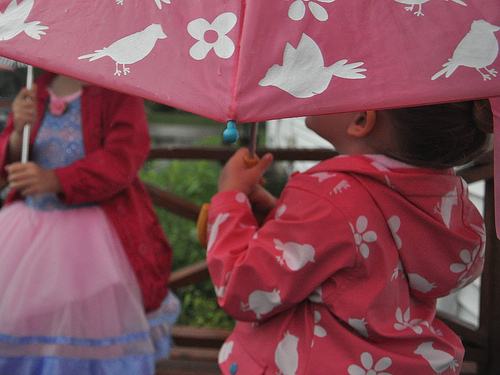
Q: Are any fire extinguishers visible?
A: No, there are no fire extinguishers.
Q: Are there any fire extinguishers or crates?
A: No, there are no fire extinguishers or crates.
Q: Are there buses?
A: No, there are no buses.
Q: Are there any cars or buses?
A: No, there are no buses or cars.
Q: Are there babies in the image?
A: Yes, there is a baby.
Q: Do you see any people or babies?
A: Yes, there is a baby.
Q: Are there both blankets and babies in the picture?
A: No, there is a baby but no blankets.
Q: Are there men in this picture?
A: No, there are no men.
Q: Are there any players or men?
A: No, there are no men or players.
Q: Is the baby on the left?
A: Yes, the baby is on the left of the image.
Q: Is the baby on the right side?
A: No, the baby is on the left of the image.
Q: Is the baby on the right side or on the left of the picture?
A: The baby is on the left of the image.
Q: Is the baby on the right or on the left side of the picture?
A: The baby is on the left of the image.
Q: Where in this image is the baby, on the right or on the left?
A: The baby is on the left of the image.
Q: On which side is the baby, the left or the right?
A: The baby is on the left of the image.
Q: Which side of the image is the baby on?
A: The baby is on the left of the image.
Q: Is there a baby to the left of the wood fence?
A: Yes, there is a baby to the left of the fence.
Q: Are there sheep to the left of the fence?
A: No, there is a baby to the left of the fence.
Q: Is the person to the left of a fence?
A: Yes, the baby is to the left of a fence.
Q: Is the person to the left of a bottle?
A: No, the baby is to the left of a fence.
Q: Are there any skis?
A: No, there are no skis.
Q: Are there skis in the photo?
A: No, there are no skis.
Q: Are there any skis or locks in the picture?
A: No, there are no skis or locks.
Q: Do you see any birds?
A: Yes, there is a bird.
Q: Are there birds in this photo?
A: Yes, there is a bird.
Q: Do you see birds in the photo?
A: Yes, there is a bird.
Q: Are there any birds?
A: Yes, there is a bird.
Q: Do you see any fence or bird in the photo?
A: Yes, there is a bird.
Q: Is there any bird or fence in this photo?
A: Yes, there is a bird.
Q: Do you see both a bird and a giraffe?
A: No, there is a bird but no giraffes.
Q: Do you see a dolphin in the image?
A: No, there are no dolphins.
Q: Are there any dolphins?
A: No, there are no dolphins.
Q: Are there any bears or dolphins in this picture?
A: No, there are no dolphins or bears.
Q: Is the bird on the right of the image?
A: No, the bird is on the left of the image.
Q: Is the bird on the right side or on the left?
A: The bird is on the left of the image.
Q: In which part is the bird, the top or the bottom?
A: The bird is in the top of the image.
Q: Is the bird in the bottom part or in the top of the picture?
A: The bird is in the top of the image.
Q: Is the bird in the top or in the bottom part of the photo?
A: The bird is in the top of the image.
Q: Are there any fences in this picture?
A: Yes, there is a fence.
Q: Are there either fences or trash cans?
A: Yes, there is a fence.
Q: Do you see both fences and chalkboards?
A: No, there is a fence but no chalkboards.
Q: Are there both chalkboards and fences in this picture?
A: No, there is a fence but no chalkboards.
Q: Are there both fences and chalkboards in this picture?
A: No, there is a fence but no chalkboards.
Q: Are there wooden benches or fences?
A: Yes, there is a wood fence.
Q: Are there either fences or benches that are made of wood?
A: Yes, the fence is made of wood.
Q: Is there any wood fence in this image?
A: Yes, there is a wood fence.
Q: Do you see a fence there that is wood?
A: Yes, there is a wood fence.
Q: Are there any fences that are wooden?
A: Yes, there is a fence that is wooden.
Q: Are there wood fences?
A: Yes, there is a fence that is made of wood.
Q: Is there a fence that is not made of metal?
A: Yes, there is a fence that is made of wood.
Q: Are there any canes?
A: No, there are no canes.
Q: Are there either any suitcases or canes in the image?
A: No, there are no canes or suitcases.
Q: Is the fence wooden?
A: Yes, the fence is wooden.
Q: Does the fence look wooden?
A: Yes, the fence is wooden.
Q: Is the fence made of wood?
A: Yes, the fence is made of wood.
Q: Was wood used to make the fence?
A: Yes, the fence is made of wood.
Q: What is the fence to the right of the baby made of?
A: The fence is made of wood.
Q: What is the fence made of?
A: The fence is made of wood.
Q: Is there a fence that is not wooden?
A: No, there is a fence but it is wooden.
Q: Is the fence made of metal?
A: No, the fence is made of wood.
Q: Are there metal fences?
A: No, there is a fence but it is made of wood.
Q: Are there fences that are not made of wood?
A: No, there is a fence but it is made of wood.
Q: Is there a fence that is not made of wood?
A: No, there is a fence but it is made of wood.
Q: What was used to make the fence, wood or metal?
A: The fence is made of wood.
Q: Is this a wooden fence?
A: Yes, this is a wooden fence.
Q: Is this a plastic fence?
A: No, this is a wooden fence.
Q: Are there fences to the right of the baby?
A: Yes, there is a fence to the right of the baby.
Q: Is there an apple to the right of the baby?
A: No, there is a fence to the right of the baby.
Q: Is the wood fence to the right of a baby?
A: Yes, the fence is to the right of a baby.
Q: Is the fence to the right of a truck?
A: No, the fence is to the right of a baby.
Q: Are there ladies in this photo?
A: No, there are no ladies.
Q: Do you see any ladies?
A: No, there are no ladies.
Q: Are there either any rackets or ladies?
A: No, there are no ladies or rackets.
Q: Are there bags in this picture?
A: No, there are no bags.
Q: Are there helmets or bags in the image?
A: No, there are no bags or helmets.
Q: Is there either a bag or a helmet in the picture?
A: No, there are no bags or helmets.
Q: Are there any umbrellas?
A: Yes, there is an umbrella.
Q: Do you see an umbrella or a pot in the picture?
A: Yes, there is an umbrella.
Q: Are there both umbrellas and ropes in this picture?
A: No, there is an umbrella but no ropes.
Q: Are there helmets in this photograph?
A: No, there are no helmets.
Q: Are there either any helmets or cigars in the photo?
A: No, there are no helmets or cigars.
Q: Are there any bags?
A: No, there are no bags.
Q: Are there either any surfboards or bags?
A: No, there are no bags or surfboards.